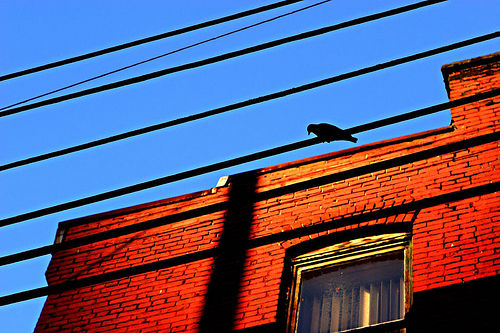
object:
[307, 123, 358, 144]
bird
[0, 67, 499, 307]
wire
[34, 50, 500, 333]
building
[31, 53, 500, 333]
bricks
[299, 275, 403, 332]
blinds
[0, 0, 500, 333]
sky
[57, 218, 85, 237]
corner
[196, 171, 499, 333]
shadow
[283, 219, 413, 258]
arch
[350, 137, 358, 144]
tail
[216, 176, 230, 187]
white mark